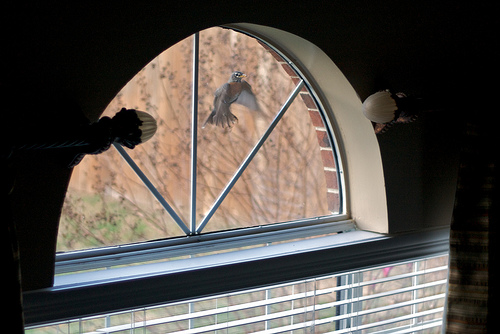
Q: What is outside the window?
A: Bird outside of an arched window.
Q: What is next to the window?
A: Curtain panel next to the window.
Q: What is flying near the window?
A: A bird flying near a window.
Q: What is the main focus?
A: An arched window with a bird outside.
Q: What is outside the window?
A: A bird outside a window.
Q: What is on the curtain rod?
A: A finial on a curtain rod.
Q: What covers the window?
A: Blinds.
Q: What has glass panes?
A: Window.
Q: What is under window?
A: Sill.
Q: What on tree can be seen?
A: Branches and leaves.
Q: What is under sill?
A: Window.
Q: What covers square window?
A: Blinds.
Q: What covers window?
A: Curtain.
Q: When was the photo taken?
A: During the day.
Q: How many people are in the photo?
A: None.